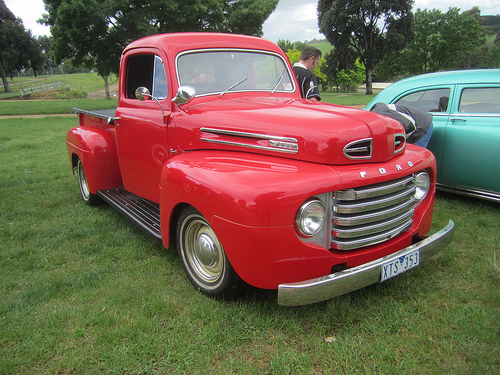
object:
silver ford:
[64, 32, 456, 308]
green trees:
[314, 0, 415, 95]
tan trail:
[0, 110, 78, 120]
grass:
[76, 77, 96, 89]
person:
[369, 102, 434, 148]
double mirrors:
[134, 85, 197, 105]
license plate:
[379, 251, 420, 283]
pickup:
[63, 32, 455, 307]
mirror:
[132, 86, 150, 103]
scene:
[0, 0, 498, 121]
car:
[361, 68, 499, 205]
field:
[0, 116, 499, 372]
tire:
[173, 206, 241, 298]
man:
[288, 47, 323, 101]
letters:
[380, 265, 388, 281]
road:
[0, 78, 118, 118]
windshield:
[175, 50, 293, 96]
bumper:
[277, 220, 456, 308]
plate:
[378, 249, 421, 284]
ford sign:
[357, 161, 413, 179]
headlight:
[297, 201, 326, 236]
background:
[0, 0, 499, 134]